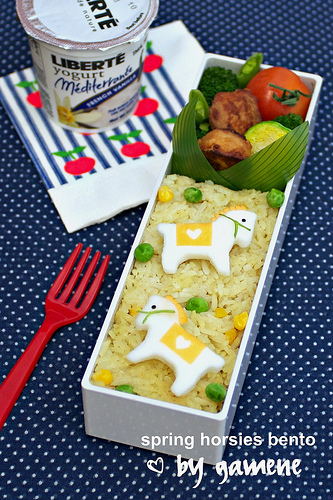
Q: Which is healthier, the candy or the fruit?
A: The fruit is healthier than the candy.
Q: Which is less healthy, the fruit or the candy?
A: The candy is less healthy than the fruit.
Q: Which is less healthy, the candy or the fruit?
A: The candy is less healthy than the fruit.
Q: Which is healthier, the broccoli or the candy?
A: The broccoli is healthier than the candy.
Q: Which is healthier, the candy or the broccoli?
A: The broccoli is healthier than the candy.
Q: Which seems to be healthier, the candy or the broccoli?
A: The broccoli is healthier than the candy.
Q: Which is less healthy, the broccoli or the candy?
A: The candy is less healthy than the broccoli.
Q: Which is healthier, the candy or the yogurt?
A: The yogurt is healthier than the candy.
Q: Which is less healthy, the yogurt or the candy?
A: The candy is less healthy than the yogurt.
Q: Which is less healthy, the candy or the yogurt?
A: The candy is less healthy than the yogurt.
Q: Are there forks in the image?
A: Yes, there is a fork.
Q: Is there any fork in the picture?
A: Yes, there is a fork.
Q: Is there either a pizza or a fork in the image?
A: Yes, there is a fork.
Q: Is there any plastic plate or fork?
A: Yes, there is a plastic fork.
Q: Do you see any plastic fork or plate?
A: Yes, there is a plastic fork.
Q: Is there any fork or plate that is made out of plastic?
A: Yes, the fork is made of plastic.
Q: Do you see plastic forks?
A: Yes, there is a fork that is made of plastic.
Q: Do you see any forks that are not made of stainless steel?
A: Yes, there is a fork that is made of plastic.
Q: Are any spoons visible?
A: No, there are no spoons.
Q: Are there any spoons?
A: No, there are no spoons.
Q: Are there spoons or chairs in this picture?
A: No, there are no spoons or chairs.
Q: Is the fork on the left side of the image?
A: Yes, the fork is on the left of the image.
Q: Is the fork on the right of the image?
A: No, the fork is on the left of the image.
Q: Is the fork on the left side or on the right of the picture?
A: The fork is on the left of the image.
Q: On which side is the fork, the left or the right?
A: The fork is on the left of the image.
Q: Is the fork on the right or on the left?
A: The fork is on the left of the image.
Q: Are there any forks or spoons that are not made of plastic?
A: No, there is a fork but it is made of plastic.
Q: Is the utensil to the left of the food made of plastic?
A: Yes, the fork is made of plastic.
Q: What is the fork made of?
A: The fork is made of plastic.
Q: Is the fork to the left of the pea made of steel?
A: No, the fork is made of plastic.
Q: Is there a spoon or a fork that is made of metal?
A: No, there is a fork but it is made of plastic.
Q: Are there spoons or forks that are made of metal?
A: No, there is a fork but it is made of plastic.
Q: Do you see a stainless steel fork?
A: No, there is a fork but it is made of plastic.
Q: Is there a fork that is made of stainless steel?
A: No, there is a fork but it is made of plastic.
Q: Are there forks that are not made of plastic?
A: No, there is a fork but it is made of plastic.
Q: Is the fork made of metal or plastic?
A: The fork is made of plastic.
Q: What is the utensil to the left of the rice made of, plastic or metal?
A: The fork is made of plastic.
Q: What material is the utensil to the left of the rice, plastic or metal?
A: The fork is made of plastic.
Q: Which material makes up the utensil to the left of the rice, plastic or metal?
A: The fork is made of plastic.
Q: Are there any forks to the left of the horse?
A: Yes, there is a fork to the left of the horse.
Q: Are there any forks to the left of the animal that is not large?
A: Yes, there is a fork to the left of the horse.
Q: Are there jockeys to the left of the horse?
A: No, there is a fork to the left of the horse.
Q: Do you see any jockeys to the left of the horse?
A: No, there is a fork to the left of the horse.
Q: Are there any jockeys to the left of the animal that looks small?
A: No, there is a fork to the left of the horse.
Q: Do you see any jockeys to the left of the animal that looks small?
A: No, there is a fork to the left of the horse.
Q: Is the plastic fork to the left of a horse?
A: Yes, the fork is to the left of a horse.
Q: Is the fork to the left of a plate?
A: No, the fork is to the left of a horse.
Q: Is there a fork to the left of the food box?
A: Yes, there is a fork to the left of the box.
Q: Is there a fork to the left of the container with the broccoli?
A: Yes, there is a fork to the left of the box.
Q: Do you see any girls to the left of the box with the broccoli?
A: No, there is a fork to the left of the box.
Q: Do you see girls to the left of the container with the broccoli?
A: No, there is a fork to the left of the box.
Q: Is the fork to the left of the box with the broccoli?
A: Yes, the fork is to the left of the box.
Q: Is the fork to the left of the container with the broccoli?
A: Yes, the fork is to the left of the box.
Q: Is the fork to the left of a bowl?
A: No, the fork is to the left of the box.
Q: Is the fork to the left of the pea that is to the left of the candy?
A: Yes, the fork is to the left of the pea.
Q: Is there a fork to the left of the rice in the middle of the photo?
A: Yes, there is a fork to the left of the rice.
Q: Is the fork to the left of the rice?
A: Yes, the fork is to the left of the rice.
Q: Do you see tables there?
A: Yes, there is a table.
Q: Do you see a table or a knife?
A: Yes, there is a table.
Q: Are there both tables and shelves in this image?
A: No, there is a table but no shelves.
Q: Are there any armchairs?
A: No, there are no armchairs.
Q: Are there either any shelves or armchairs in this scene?
A: No, there are no armchairs or shelves.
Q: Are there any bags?
A: No, there are no bags.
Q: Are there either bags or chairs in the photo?
A: No, there are no bags or chairs.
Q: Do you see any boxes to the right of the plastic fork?
A: Yes, there is a box to the right of the fork.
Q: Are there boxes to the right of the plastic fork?
A: Yes, there is a box to the right of the fork.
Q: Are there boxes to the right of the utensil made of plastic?
A: Yes, there is a box to the right of the fork.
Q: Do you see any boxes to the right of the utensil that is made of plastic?
A: Yes, there is a box to the right of the fork.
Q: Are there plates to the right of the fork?
A: No, there is a box to the right of the fork.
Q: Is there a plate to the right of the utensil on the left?
A: No, there is a box to the right of the fork.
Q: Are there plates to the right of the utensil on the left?
A: No, there is a box to the right of the fork.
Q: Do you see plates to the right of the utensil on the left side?
A: No, there is a box to the right of the fork.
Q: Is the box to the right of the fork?
A: Yes, the box is to the right of the fork.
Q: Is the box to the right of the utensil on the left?
A: Yes, the box is to the right of the fork.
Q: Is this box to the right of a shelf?
A: No, the box is to the right of the fork.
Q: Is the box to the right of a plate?
A: No, the box is to the right of the tablecloth.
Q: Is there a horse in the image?
A: Yes, there is a horse.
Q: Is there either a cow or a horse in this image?
A: Yes, there is a horse.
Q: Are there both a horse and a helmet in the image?
A: No, there is a horse but no helmets.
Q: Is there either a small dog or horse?
A: Yes, there is a small horse.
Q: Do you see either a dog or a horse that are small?
A: Yes, the horse is small.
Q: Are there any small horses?
A: Yes, there is a small horse.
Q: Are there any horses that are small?
A: Yes, there is a horse that is small.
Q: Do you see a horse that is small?
A: Yes, there is a horse that is small.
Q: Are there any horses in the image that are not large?
A: Yes, there is a small horse.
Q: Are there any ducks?
A: No, there are no ducks.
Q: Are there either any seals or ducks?
A: No, there are no ducks or seals.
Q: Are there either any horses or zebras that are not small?
A: No, there is a horse but it is small.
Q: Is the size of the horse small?
A: Yes, the horse is small.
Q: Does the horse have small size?
A: Yes, the horse is small.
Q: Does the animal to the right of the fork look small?
A: Yes, the horse is small.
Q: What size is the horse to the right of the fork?
A: The horse is small.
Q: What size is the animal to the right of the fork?
A: The horse is small.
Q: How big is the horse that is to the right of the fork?
A: The horse is small.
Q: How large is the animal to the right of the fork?
A: The horse is small.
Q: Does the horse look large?
A: No, the horse is small.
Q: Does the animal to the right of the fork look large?
A: No, the horse is small.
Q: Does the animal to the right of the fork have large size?
A: No, the horse is small.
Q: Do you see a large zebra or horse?
A: No, there is a horse but it is small.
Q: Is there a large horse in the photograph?
A: No, there is a horse but it is small.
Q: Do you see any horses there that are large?
A: No, there is a horse but it is small.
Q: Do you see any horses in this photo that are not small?
A: No, there is a horse but it is small.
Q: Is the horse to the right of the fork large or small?
A: The horse is small.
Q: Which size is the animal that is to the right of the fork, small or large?
A: The horse is small.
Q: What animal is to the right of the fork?
A: The animal is a horse.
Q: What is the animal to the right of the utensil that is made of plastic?
A: The animal is a horse.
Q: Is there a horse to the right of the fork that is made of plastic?
A: Yes, there is a horse to the right of the fork.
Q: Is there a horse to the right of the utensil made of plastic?
A: Yes, there is a horse to the right of the fork.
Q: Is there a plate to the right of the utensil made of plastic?
A: No, there is a horse to the right of the fork.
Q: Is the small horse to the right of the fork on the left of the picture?
A: Yes, the horse is to the right of the fork.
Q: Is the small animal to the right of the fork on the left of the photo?
A: Yes, the horse is to the right of the fork.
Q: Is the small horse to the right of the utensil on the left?
A: Yes, the horse is to the right of the fork.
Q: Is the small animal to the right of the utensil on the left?
A: Yes, the horse is to the right of the fork.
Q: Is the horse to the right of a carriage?
A: No, the horse is to the right of the fork.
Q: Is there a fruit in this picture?
A: Yes, there is a fruit.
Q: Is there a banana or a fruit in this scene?
A: Yes, there is a fruit.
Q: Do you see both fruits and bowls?
A: No, there is a fruit but no bowls.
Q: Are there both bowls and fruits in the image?
A: No, there is a fruit but no bowls.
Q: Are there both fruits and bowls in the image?
A: No, there is a fruit but no bowls.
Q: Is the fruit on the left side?
A: No, the fruit is on the right of the image.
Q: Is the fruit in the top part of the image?
A: Yes, the fruit is in the top of the image.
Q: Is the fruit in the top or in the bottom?
A: The fruit is in the top of the image.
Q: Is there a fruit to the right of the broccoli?
A: Yes, there is a fruit to the right of the broccoli.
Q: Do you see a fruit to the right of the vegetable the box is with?
A: Yes, there is a fruit to the right of the broccoli.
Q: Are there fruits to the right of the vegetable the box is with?
A: Yes, there is a fruit to the right of the broccoli.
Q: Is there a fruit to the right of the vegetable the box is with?
A: Yes, there is a fruit to the right of the broccoli.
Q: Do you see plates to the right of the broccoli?
A: No, there is a fruit to the right of the broccoli.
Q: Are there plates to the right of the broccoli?
A: No, there is a fruit to the right of the broccoli.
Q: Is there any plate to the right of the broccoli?
A: No, there is a fruit to the right of the broccoli.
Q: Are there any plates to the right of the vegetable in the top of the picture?
A: No, there is a fruit to the right of the broccoli.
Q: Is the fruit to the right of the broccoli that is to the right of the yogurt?
A: Yes, the fruit is to the right of the broccoli.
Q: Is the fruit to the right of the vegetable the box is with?
A: Yes, the fruit is to the right of the broccoli.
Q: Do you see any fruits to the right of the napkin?
A: Yes, there is a fruit to the right of the napkin.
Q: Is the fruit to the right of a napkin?
A: Yes, the fruit is to the right of a napkin.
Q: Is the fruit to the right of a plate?
A: No, the fruit is to the right of a napkin.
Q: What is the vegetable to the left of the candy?
A: The vegetable is a pea.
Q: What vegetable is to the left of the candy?
A: The vegetable is a pea.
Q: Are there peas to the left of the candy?
A: Yes, there is a pea to the left of the candy.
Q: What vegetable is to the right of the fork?
A: The vegetable is a pea.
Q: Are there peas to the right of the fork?
A: Yes, there is a pea to the right of the fork.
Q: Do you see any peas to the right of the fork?
A: Yes, there is a pea to the right of the fork.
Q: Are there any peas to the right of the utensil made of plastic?
A: Yes, there is a pea to the right of the fork.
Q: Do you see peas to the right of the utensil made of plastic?
A: Yes, there is a pea to the right of the fork.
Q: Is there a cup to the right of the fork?
A: No, there is a pea to the right of the fork.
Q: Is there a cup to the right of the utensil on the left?
A: No, there is a pea to the right of the fork.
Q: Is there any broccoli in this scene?
A: Yes, there is broccoli.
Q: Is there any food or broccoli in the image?
A: Yes, there is broccoli.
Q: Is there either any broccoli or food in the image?
A: Yes, there is broccoli.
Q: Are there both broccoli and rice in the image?
A: Yes, there are both broccoli and rice.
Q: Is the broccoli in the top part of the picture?
A: Yes, the broccoli is in the top of the image.